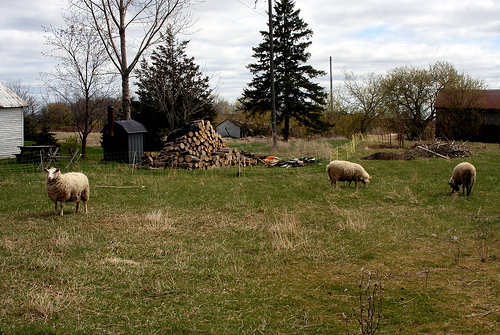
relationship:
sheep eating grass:
[441, 156, 482, 201] [0, 130, 498, 332]